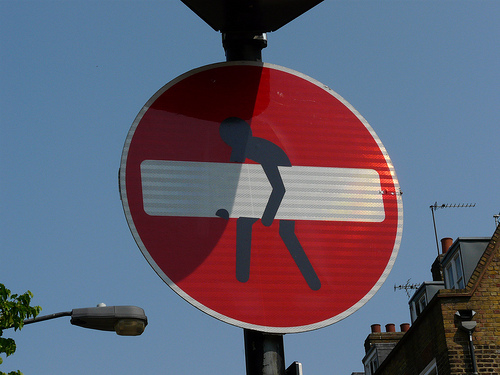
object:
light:
[69, 301, 148, 337]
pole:
[0, 308, 70, 329]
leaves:
[28, 304, 41, 320]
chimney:
[440, 237, 452, 254]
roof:
[434, 234, 492, 263]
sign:
[118, 58, 406, 334]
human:
[216, 117, 322, 290]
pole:
[218, 30, 290, 374]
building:
[352, 220, 498, 375]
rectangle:
[139, 158, 386, 223]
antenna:
[428, 202, 477, 259]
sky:
[1, 0, 498, 374]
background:
[1, 1, 497, 372]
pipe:
[453, 306, 482, 374]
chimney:
[368, 322, 382, 335]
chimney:
[384, 322, 397, 335]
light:
[177, 0, 324, 33]